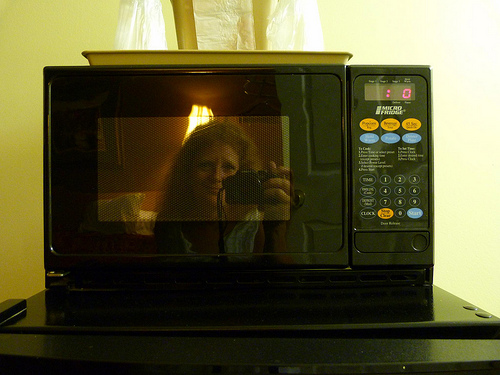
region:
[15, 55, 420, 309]
black microwave on table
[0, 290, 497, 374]
black table in kitchen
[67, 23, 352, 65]
small tray on microwave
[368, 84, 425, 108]
red timer on microwave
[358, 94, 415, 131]
round and yellow buttons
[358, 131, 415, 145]
round and blue buttons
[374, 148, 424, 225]
number pad on microwave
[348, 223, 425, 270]
door latch on microwave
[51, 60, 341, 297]
black door on microwave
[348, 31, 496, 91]
yellow wall behind microwave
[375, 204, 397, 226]
button on small microwave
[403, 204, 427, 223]
button on small microwave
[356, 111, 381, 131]
button on small microwave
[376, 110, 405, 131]
button on small microwave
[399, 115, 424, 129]
button on small microwave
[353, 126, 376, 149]
button on small microwave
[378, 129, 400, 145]
button on small microwave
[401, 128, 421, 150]
button on small microwave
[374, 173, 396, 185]
button on small microwave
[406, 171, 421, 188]
button on small microwave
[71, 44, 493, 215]
a kitchen microwave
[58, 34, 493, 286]
a black kitchen microwavve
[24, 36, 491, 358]
a kitchen microwave plugged in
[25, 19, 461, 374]
a microwave on table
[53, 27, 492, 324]
microwave on the fridge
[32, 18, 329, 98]
a pan on a microwave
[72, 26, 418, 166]
a pan on a black microwave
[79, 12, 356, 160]
a pan on a kitchen microwave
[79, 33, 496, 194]
a pan on a black kitchen microwave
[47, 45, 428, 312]
a microwave that is black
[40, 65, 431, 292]
black color microwave oven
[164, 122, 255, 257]
reflection image of woman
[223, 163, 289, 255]
woman holding camera in hand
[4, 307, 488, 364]
black table on which microwave is kept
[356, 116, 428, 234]
control panel of the microwave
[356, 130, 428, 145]
blue button appearing on control panel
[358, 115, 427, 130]
yellow button on control panel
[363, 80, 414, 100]
digital displayed indicator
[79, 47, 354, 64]
tray kept on microwave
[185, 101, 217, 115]
Light lit inside microwave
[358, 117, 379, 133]
orange button the black microwave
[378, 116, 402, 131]
orange button the black microwave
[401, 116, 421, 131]
orange button the black microwave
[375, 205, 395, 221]
orange button the black microwave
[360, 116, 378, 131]
button on a microwave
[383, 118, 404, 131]
button on a microwave